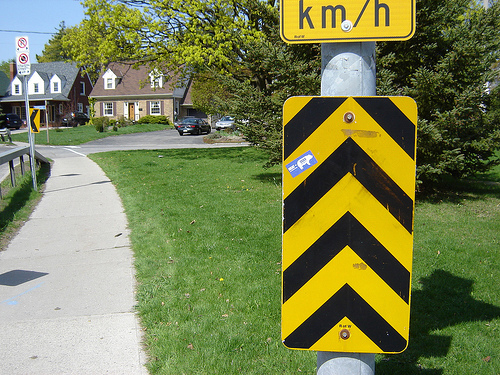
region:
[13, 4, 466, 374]
a European city street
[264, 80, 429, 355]
a yellow and black warning sign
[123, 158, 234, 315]
a green lawn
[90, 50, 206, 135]
a very nice house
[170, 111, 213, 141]
a small family car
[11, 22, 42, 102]
no parking sign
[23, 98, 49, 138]
left turn warning sign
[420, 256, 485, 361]
the shadow of a sign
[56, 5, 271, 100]
yellow flowers on a tree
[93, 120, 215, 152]
a family's home driveway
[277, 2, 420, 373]
yellow and black traffic sign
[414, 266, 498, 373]
shadow of the traffic sign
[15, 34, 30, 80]
traffic signs to left of yellow and black sign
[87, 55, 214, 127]
brown house behind the traffic signs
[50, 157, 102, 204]
sidewalk behind the traffic signs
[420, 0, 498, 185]
evergreen to right of traffic sign in foreground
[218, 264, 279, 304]
grass behind the yellow and black traffic sign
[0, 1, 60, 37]
sky above the house on the left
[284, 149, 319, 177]
sticker on the foreground traffic sign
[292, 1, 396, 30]
writing above the up arrows on traffic sign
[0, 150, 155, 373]
a gray sidewalk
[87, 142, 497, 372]
a green yard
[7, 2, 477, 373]
a scene outside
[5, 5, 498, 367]
a scene happening during the day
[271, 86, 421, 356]
a black and yellow sign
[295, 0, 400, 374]
a gray pole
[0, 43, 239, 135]
a couple of houses in the background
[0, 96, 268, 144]
a few cars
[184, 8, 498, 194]
a green trees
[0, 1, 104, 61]
a blue sky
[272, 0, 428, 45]
Speed limit sign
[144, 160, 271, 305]
Green grass with yellow dandelions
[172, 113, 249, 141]
Cars parked in the driveway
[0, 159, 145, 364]
Gray concrete sidewalk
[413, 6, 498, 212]
Evergreen trees next to the path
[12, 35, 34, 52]
No parking sign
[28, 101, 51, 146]
Black arrow indicating curve on the road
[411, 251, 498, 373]
Shadow from the sign post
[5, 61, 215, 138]
Houses in neighborhood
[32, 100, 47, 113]
Blue street sign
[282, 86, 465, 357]
street sign is yellow and black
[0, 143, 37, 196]
guard rail on the road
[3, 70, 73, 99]
three windows on the house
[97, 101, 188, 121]
brown shutters on the house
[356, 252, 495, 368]
street sign shadow in the grass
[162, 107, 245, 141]
cars in the driveway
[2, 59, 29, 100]
chimney on the house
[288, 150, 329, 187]
sticker on the street sign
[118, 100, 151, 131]
front door of the house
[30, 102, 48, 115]
street sign is blue and white